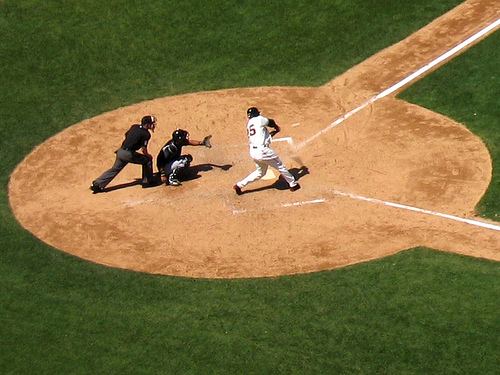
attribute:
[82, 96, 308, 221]
people — baseball field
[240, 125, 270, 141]
number — jersey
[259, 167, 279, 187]
base — white 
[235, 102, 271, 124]
helmet —  black baseball 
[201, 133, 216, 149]
glove — large baseball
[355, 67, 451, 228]
line —  long white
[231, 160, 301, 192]
pants —  man's white 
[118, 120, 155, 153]
sleeve shirt — man's black short 